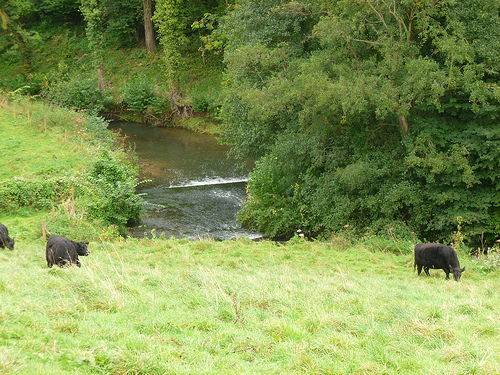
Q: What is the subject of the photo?
A: Animals.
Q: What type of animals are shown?
A: Cows.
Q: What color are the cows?
A: Black.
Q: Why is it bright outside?
A: It's daytime.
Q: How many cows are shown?
A: Four.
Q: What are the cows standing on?
A: Grass.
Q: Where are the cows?
A: Field.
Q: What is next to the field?
A: Stream.